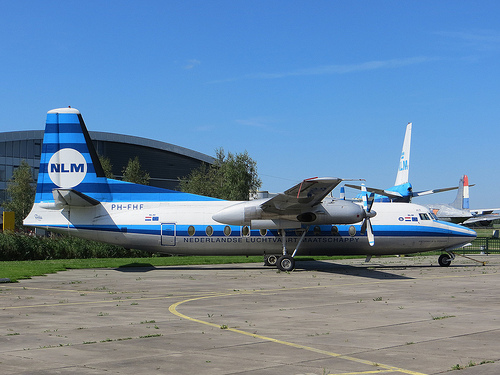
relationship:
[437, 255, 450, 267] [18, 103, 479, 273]
wheel on front of plane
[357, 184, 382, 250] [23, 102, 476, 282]
propeller on airplane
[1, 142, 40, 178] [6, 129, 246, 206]
windows in side of building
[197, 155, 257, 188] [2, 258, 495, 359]
hedge on ground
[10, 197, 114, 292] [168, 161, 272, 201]
post behind hedge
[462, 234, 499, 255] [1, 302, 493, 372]
fence in background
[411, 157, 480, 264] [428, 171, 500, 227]
nose of airplane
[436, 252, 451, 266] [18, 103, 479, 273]
front wheel of plane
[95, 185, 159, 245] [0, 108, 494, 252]
letters phfhf on side of plane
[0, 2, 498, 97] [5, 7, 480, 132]
clouds in sky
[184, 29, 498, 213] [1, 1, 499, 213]
clouds in sky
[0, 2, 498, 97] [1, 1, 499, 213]
clouds in sky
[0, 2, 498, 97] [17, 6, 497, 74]
clouds in sky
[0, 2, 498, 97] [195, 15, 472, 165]
clouds in sky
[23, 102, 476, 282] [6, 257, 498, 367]
airplane on runway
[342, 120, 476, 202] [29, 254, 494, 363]
airplane parked on runway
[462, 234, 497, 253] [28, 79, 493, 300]
fence behind plane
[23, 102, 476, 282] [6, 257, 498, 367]
airplane parked on runway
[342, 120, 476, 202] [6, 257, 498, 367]
airplane parked on runway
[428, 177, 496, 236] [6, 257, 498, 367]
airplane parked on runway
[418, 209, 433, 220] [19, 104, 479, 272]
windows on aircraft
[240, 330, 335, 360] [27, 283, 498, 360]
lines on tarmac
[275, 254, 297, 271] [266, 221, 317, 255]
tire on gear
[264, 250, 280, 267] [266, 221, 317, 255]
tire on gear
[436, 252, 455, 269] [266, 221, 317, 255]
tire on gear